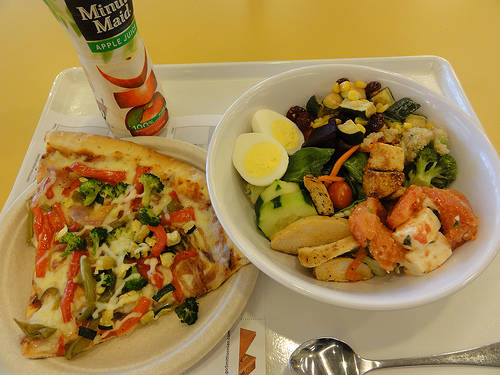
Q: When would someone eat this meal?
A: Lunch or dinner.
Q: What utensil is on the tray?
A: Silver spoon.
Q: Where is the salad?
A: On the right.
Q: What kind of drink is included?
A: Juice.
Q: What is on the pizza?
A: Vegetables.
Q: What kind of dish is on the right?
A: White bowl.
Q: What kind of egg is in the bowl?
A: Boiled egg.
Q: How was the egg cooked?
A: Boiled.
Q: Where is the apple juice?
A: Above the pizza.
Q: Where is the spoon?
A: On the bottom of the tray.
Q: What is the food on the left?
A: A slice of pizza.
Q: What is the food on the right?
A: A salad.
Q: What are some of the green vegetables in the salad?
A: Broccoli, spinach, cucumber.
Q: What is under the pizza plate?
A: A piece of paper.